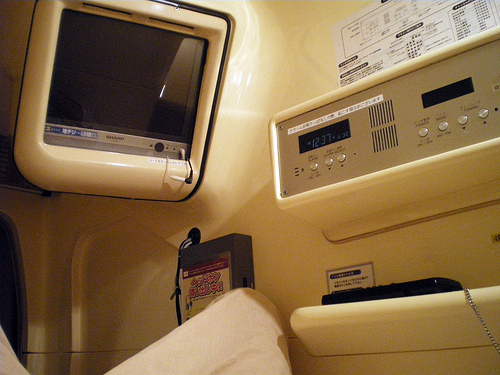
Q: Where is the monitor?
A: Wall.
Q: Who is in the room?
A: No one.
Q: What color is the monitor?
A: Cream.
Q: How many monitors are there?
A: One.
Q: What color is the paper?
A: White.